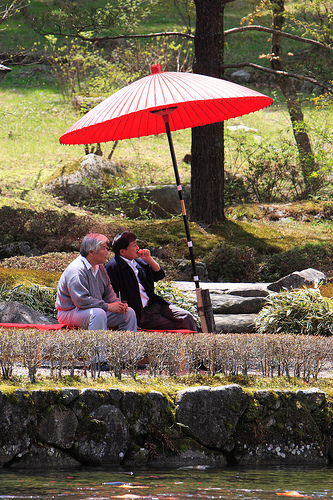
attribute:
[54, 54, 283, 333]
umbrella — red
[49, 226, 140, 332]
person — ear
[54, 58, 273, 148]
umbrella — red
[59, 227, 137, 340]
person — nose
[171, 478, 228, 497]
water — in the river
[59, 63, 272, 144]
umbrella — red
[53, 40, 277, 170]
umbrella — red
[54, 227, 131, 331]
person — leg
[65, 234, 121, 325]
person — ear